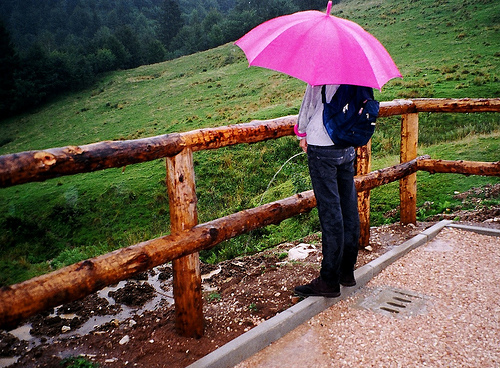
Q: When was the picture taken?
A: During the day.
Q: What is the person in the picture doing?
A: Peeing.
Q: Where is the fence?
A: In front of the man.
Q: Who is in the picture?
A: A man.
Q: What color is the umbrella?
A: Pink.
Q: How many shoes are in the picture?
A: 2.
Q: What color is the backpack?
A: Blue.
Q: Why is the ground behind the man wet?
A: From the rain.